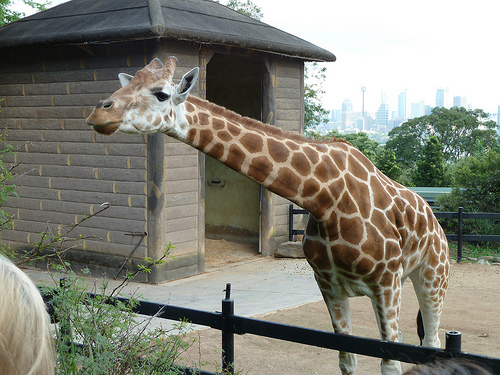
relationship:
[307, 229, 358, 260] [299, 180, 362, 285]
part of a of chest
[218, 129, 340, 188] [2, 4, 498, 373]
spotted giraffe in zoo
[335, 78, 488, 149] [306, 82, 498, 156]
faint skycrappers in city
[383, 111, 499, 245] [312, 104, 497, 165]
green bushes on background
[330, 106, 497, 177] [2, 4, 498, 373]
an open space in zoo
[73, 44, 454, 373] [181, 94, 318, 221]
giraffe has he long neck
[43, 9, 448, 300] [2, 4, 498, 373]
bright day in zoo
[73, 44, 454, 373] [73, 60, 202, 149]
giraffe has head of a giraffe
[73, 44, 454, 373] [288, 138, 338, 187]
giraffe has brown spots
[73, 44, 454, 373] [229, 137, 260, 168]
giraffe has white lines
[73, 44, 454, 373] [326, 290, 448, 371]
giraffe has legs of the giraffe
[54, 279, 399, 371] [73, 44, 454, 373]
fence in front of giraffe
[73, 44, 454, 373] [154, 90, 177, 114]
giraffe has eye of the giraffe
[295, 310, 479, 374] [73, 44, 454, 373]
dirt under giraffe under giraffe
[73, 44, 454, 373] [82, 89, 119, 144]
giraffe has nose and mouth